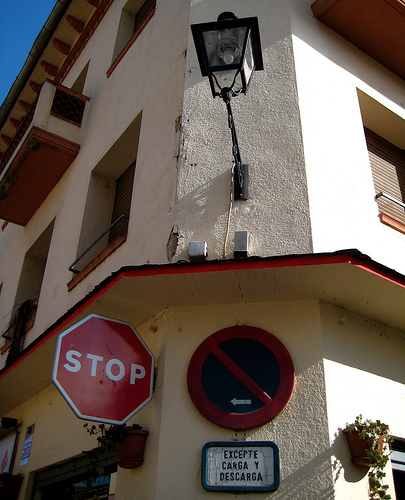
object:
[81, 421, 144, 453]
plant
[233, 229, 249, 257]
power box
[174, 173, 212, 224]
wall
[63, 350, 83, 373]
white letter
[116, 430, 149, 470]
pot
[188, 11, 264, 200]
black light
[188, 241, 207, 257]
electrical box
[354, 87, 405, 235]
window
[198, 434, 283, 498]
sign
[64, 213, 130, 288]
balcony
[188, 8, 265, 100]
light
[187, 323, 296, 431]
sign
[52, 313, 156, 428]
red sign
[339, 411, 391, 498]
potted plant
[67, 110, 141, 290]
window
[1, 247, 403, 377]
red trim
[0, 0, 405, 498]
building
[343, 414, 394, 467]
flower pot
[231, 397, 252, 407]
arrow